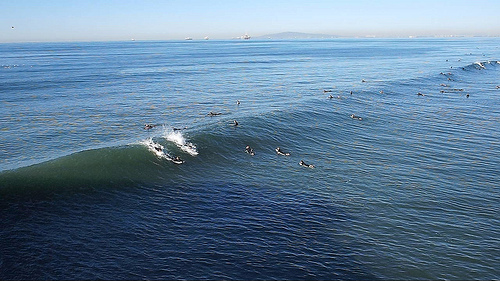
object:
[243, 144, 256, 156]
individuals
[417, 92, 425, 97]
person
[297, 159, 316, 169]
people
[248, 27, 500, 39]
mountain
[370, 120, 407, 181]
ground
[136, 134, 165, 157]
splash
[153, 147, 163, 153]
surfer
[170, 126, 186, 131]
surfer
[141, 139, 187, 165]
boats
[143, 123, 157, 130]
people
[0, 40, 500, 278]
ocean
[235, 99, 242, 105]
person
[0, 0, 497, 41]
sky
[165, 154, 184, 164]
person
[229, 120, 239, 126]
person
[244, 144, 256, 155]
person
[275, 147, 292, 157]
people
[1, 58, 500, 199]
wave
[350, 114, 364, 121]
person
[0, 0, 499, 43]
cloud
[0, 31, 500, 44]
distance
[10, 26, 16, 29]
item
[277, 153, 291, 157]
surfboards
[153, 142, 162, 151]
person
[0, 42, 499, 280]
water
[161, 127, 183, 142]
splashes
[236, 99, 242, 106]
person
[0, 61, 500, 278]
ripple